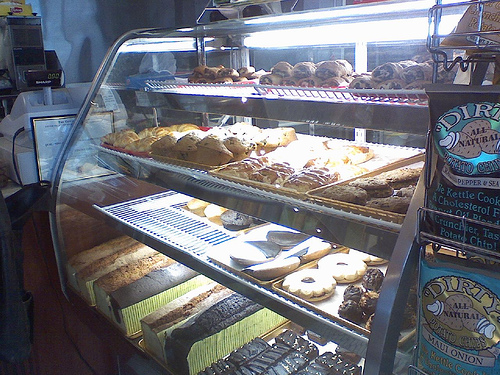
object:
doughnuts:
[254, 157, 290, 188]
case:
[36, 3, 483, 364]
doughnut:
[288, 161, 348, 196]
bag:
[425, 92, 499, 248]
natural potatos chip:
[434, 105, 499, 177]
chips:
[412, 253, 497, 374]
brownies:
[290, 332, 317, 356]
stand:
[0, 172, 47, 369]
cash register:
[0, 68, 144, 185]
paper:
[28, 108, 124, 188]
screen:
[22, 66, 65, 90]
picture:
[1, 1, 499, 374]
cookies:
[281, 267, 338, 301]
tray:
[156, 119, 304, 173]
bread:
[164, 288, 263, 371]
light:
[229, 17, 469, 54]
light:
[123, 30, 229, 55]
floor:
[4, 168, 172, 374]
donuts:
[233, 235, 283, 269]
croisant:
[267, 61, 290, 77]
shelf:
[136, 68, 437, 109]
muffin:
[195, 136, 230, 167]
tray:
[272, 246, 422, 343]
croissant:
[105, 129, 136, 146]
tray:
[99, 113, 214, 158]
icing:
[278, 340, 316, 372]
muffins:
[168, 134, 202, 160]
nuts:
[341, 360, 357, 373]